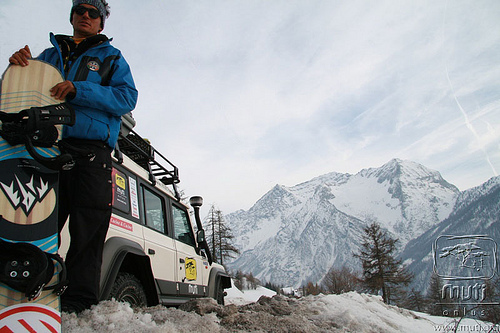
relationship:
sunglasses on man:
[59, 10, 128, 32] [16, 0, 117, 320]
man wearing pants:
[9, 0, 135, 309] [35, 149, 113, 316]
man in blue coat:
[9, 0, 135, 309] [33, 32, 138, 144]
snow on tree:
[375, 289, 414, 319] [358, 227, 413, 314]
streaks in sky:
[451, 97, 485, 154] [400, 97, 444, 151]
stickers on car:
[114, 168, 149, 219] [97, 152, 228, 309]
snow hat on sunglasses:
[100, 2, 119, 19] [62, 5, 105, 23]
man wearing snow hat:
[9, 0, 135, 309] [71, 2, 113, 22]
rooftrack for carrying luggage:
[119, 120, 185, 187] [121, 131, 158, 170]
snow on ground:
[66, 274, 495, 331] [6, 283, 486, 329]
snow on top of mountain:
[227, 172, 492, 302] [207, 159, 498, 324]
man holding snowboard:
[9, 0, 135, 309] [3, 48, 71, 330]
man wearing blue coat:
[9, 0, 141, 312] [32, 32, 138, 148]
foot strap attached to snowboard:
[4, 239, 69, 301] [13, 43, 90, 304]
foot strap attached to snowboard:
[3, 104, 78, 173] [13, 43, 90, 304]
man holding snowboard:
[9, 0, 141, 312] [2, 57, 67, 331]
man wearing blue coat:
[9, 0, 135, 309] [32, 32, 138, 148]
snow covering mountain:
[227, 172, 492, 302] [201, 156, 459, 298]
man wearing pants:
[9, 0, 141, 312] [47, 134, 117, 319]